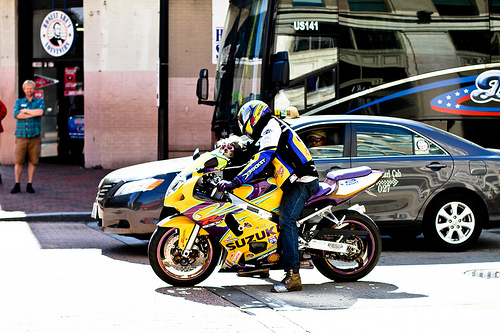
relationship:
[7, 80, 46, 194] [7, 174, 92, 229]
man in sidewalk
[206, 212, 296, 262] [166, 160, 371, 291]
suzuki in motorcylce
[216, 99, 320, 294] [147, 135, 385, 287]
man in bike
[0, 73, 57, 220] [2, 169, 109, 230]
man in sidewalk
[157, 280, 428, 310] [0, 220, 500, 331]
motorbike's shadow on road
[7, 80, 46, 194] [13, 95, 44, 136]
man wearing shirt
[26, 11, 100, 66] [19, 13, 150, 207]
sign on window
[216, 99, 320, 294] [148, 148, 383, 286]
man on motorcycle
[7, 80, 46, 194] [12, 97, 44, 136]
man wearing green shirt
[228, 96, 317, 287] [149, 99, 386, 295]
man riding bicycle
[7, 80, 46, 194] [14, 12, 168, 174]
man standing shop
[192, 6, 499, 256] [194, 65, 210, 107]
bus has mirror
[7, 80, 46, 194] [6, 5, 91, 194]
man on door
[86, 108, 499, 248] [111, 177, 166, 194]
car has headlight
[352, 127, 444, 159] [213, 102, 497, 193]
window on car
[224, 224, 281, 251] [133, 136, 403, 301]
suzuki on motorbike